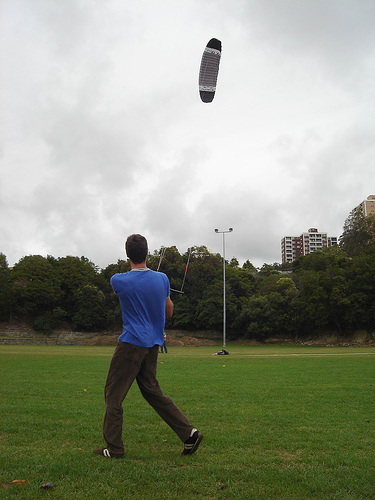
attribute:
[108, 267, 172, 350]
shirt — blue, dark blue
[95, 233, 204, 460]
man — standing, young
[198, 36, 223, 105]
kite — flying, large, grey black, white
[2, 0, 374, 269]
sky — cloudy, white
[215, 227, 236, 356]
light pole — here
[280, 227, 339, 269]
building — brick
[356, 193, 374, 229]
building — white, tall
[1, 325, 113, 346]
wall — stone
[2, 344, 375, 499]
field — green, grassy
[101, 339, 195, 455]
pants — brown, black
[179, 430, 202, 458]
shoe — black, white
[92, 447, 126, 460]
shoe — black, white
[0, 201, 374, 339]
trees — green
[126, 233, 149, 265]
hair — dark